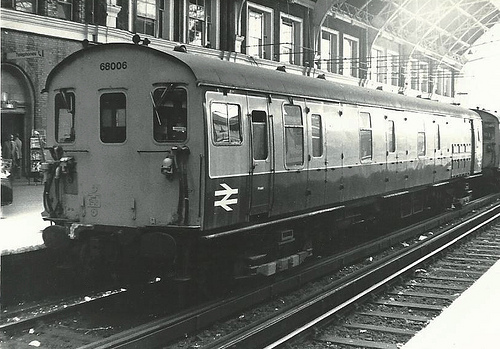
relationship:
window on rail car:
[142, 77, 198, 156] [39, 33, 500, 302]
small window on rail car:
[96, 87, 129, 155] [39, 33, 500, 302]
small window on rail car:
[46, 81, 76, 152] [39, 33, 500, 302]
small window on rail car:
[306, 107, 324, 164] [39, 33, 500, 302]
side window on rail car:
[385, 118, 396, 153] [39, 33, 500, 302]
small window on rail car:
[433, 120, 445, 153] [39, 33, 500, 302]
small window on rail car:
[53, 87, 76, 145] [39, 33, 500, 302]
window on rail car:
[247, 109, 272, 159] [39, 33, 500, 302]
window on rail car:
[282, 101, 304, 125] [39, 33, 500, 302]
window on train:
[351, 110, 383, 161] [36, 35, 498, 254]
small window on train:
[433, 120, 445, 153] [64, 23, 499, 283]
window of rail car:
[99, 91, 127, 145] [39, 33, 500, 302]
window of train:
[221, 103, 281, 164] [70, 30, 477, 266]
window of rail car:
[149, 81, 191, 145] [39, 33, 500, 302]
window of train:
[206, 102, 242, 142] [41, 32, 499, 237]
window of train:
[359, 111, 374, 162] [14, 47, 497, 276]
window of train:
[277, 94, 308, 175] [79, 45, 319, 237]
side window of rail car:
[385, 118, 396, 153] [39, 33, 500, 302]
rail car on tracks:
[39, 33, 500, 302] [3, 174, 498, 346]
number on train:
[98, 58, 130, 74] [36, 35, 498, 254]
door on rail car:
[247, 96, 271, 212] [39, 33, 500, 302]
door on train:
[247, 96, 271, 212] [475, 103, 499, 185]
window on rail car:
[149, 81, 191, 145] [39, 33, 500, 302]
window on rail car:
[95, 89, 133, 144] [39, 33, 500, 302]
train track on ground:
[264, 272, 375, 329] [0, 223, 499, 347]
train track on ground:
[43, 291, 181, 346] [0, 223, 499, 347]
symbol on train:
[211, 182, 255, 212] [41, 32, 499, 237]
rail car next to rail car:
[39, 33, 500, 302] [39, 33, 500, 302]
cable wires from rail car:
[233, 41, 320, 54] [39, 33, 500, 302]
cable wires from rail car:
[287, 52, 432, 62] [39, 33, 500, 302]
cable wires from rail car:
[318, 63, 453, 67] [39, 33, 500, 302]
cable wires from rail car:
[336, 66, 461, 72] [39, 33, 500, 302]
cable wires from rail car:
[362, 75, 477, 80] [39, 33, 500, 302]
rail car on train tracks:
[39, 33, 500, 302] [0, 170, 494, 346]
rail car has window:
[39, 33, 500, 302] [310, 113, 321, 157]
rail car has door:
[39, 33, 500, 302] [93, 82, 145, 224]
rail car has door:
[39, 33, 500, 302] [251, 97, 273, 213]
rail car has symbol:
[39, 33, 500, 302] [215, 182, 237, 213]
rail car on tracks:
[39, 33, 500, 302] [323, 237, 447, 347]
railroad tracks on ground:
[41, 183, 458, 345] [0, 173, 500, 345]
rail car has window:
[43, 17, 488, 267] [49, 85, 84, 146]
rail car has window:
[43, 17, 488, 267] [93, 82, 132, 155]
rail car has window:
[43, 17, 488, 267] [146, 80, 194, 148]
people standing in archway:
[1, 130, 31, 202] [6, 162, 66, 266]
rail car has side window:
[39, 33, 500, 302] [249, 111, 267, 158]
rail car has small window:
[39, 33, 500, 302] [311, 113, 323, 158]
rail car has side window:
[39, 33, 500, 302] [356, 107, 377, 164]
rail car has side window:
[39, 33, 500, 302] [382, 112, 394, 155]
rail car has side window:
[39, 33, 500, 302] [410, 122, 435, 156]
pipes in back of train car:
[39, 140, 80, 225] [41, 28, 276, 279]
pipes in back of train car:
[157, 145, 196, 225] [41, 28, 276, 279]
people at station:
[3, 132, 24, 177] [4, 10, 323, 299]